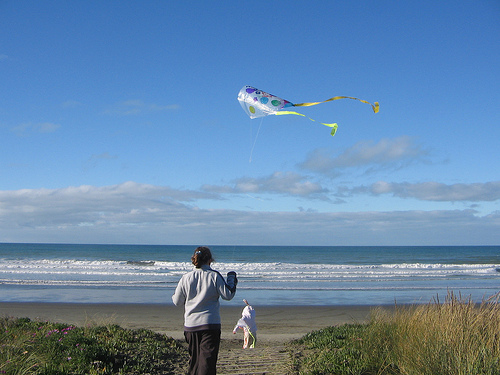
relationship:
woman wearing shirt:
[171, 245, 237, 372] [171, 266, 236, 326]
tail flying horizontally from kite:
[294, 96, 379, 114] [278, 82, 390, 146]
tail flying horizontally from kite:
[274, 111, 338, 137] [278, 82, 390, 146]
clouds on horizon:
[3, 135, 499, 245] [2, 0, 499, 246]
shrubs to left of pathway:
[304, 304, 474, 372] [193, 332, 285, 373]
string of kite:
[239, 124, 269, 175] [238, 79, 386, 140]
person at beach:
[229, 297, 268, 344] [2, 244, 499, 374]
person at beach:
[179, 244, 248, 372] [2, 244, 499, 374]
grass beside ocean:
[290, 322, 394, 374] [235, 244, 498, 303]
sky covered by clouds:
[3, 6, 484, 245] [4, 84, 498, 252]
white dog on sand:
[236, 301, 266, 354] [237, 346, 272, 373]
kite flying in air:
[218, 72, 408, 186] [49, 31, 488, 160]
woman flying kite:
[171, 245, 237, 372] [235, 83, 380, 137]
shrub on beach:
[2, 312, 194, 371] [1, 283, 497, 373]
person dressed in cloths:
[233, 299, 258, 349] [238, 306, 256, 343]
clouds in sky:
[0, 150, 497, 245] [8, 55, 499, 249]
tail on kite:
[272, 110, 339, 136] [235, 83, 380, 137]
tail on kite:
[292, 93, 380, 113] [235, 83, 380, 137]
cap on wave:
[1, 257, 498, 282] [1, 247, 498, 290]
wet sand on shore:
[0, 297, 495, 335] [209, 294, 324, 374]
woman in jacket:
[171, 246, 239, 374] [167, 268, 239, 334]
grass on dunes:
[2, 311, 190, 374] [99, 306, 404, 337]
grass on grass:
[277, 296, 498, 374] [2, 311, 190, 374]